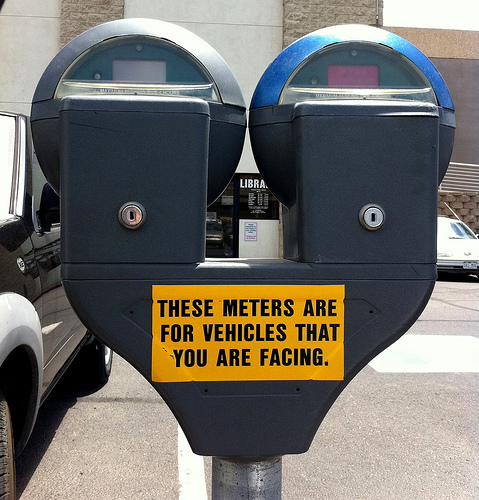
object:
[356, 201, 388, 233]
bolt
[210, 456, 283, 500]
post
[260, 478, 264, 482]
spot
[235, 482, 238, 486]
spot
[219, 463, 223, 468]
spot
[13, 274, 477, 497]
sidewalk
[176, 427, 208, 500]
line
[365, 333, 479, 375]
line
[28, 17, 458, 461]
parking meter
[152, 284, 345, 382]
sign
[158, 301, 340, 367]
wording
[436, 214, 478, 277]
car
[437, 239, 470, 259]
section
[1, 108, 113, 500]
car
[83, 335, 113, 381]
wheel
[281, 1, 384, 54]
wall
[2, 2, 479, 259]
building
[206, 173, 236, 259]
window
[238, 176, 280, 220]
window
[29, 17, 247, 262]
meter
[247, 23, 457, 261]
meter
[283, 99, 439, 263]
back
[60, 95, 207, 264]
back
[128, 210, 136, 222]
keyhole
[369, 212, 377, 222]
keyhole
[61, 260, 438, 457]
back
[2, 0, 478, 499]
parking lot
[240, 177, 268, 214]
lettering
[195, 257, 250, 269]
sunlight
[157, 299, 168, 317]
letter t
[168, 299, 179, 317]
letter h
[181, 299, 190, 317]
letter e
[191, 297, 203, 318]
letter s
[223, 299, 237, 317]
letter m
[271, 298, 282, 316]
letter r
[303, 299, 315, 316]
letter a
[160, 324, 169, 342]
letter f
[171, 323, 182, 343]
letter o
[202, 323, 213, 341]
letter v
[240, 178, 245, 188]
letter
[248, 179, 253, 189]
letter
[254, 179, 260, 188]
letter